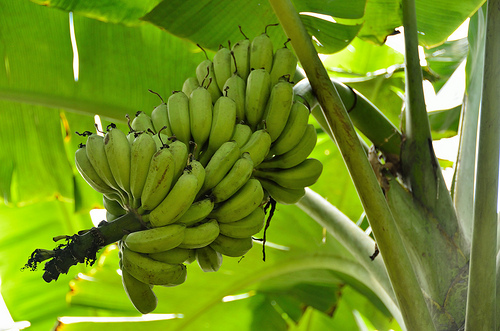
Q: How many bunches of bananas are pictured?
A: One.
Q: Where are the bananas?
A: On the tree.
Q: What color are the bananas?
A: Green.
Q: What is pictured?
A: Banana tree.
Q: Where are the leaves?
A: Above the bananas.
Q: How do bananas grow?
A: In bunches.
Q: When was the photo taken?
A: During the day.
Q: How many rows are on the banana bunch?
A: Four.